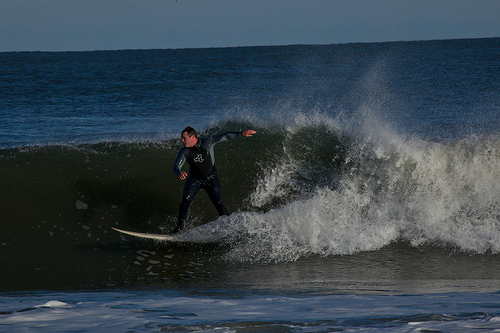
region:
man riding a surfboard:
[111, 109, 273, 261]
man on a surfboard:
[102, 113, 269, 250]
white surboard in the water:
[100, 215, 199, 250]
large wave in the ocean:
[0, 84, 479, 278]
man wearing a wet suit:
[107, 122, 272, 252]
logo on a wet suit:
[190, 148, 207, 168]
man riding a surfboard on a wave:
[98, 113, 265, 261]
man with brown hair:
[148, 117, 265, 237]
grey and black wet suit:
[165, 126, 246, 237]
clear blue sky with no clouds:
[0, 1, 498, 61]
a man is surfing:
[71, 43, 451, 273]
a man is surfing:
[101, 93, 325, 305]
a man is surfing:
[26, 66, 290, 223]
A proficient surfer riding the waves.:
[107, 122, 267, 246]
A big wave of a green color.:
[0, 103, 498, 285]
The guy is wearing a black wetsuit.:
[170, 127, 240, 232]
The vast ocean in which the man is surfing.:
[0, 35, 499, 332]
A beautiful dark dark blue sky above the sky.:
[0, 0, 498, 51]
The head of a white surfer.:
[178, 124, 200, 149]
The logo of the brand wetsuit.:
[192, 151, 207, 164]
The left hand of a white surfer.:
[241, 125, 258, 141]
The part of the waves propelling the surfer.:
[170, 102, 498, 263]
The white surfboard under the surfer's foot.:
[105, 222, 246, 243]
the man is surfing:
[133, 103, 268, 263]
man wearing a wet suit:
[170, 113, 252, 220]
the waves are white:
[223, 61, 495, 293]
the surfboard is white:
[95, 216, 206, 268]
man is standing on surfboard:
[153, 90, 280, 245]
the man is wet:
[150, 104, 295, 265]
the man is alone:
[129, 92, 280, 248]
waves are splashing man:
[112, 81, 330, 268]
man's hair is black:
[179, 117, 210, 146]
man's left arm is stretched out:
[203, 118, 270, 163]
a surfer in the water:
[67, 50, 424, 330]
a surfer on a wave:
[100, 86, 356, 302]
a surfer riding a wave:
[132, 67, 357, 289]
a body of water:
[5, 80, 156, 252]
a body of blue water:
[12, 57, 161, 192]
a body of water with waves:
[4, 30, 165, 192]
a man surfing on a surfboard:
[139, 75, 290, 245]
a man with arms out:
[103, 67, 347, 331]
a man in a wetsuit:
[122, 102, 393, 328]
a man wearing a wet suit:
[82, 68, 299, 313]